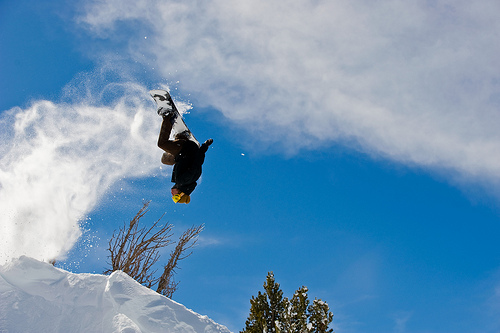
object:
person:
[157, 93, 214, 204]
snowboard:
[147, 87, 200, 148]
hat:
[177, 194, 190, 204]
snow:
[2, 15, 210, 260]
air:
[1, 0, 499, 81]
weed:
[153, 221, 207, 298]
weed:
[106, 201, 149, 270]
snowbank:
[0, 255, 234, 333]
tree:
[240, 289, 277, 332]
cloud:
[67, 1, 500, 202]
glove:
[204, 138, 214, 147]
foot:
[157, 107, 179, 120]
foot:
[174, 129, 195, 140]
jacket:
[171, 139, 210, 197]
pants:
[157, 115, 189, 166]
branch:
[308, 298, 335, 332]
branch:
[290, 284, 311, 333]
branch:
[263, 271, 291, 333]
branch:
[239, 290, 270, 333]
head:
[171, 185, 191, 204]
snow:
[159, 107, 168, 115]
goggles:
[171, 191, 184, 204]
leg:
[157, 115, 186, 155]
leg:
[161, 152, 177, 166]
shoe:
[157, 106, 179, 118]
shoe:
[173, 130, 191, 139]